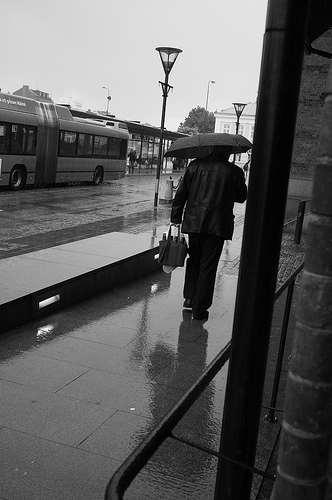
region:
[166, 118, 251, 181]
A person is using a umbrella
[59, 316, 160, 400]
The ground is slippery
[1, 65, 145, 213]
An extended passenger bus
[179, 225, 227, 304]
The man is wearing black pants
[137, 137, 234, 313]
The man is carrying a bag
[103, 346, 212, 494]
Railing alongside the sidewalk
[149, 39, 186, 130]
Tall street light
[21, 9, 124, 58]
Large body of skies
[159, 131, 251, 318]
man carrying an umbrella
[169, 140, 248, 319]
man wearing a dark jacket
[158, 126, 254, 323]
person holding a black umbrella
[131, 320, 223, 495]
the shadow on the street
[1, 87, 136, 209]
the bus is in motion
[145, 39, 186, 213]
the pole is color black